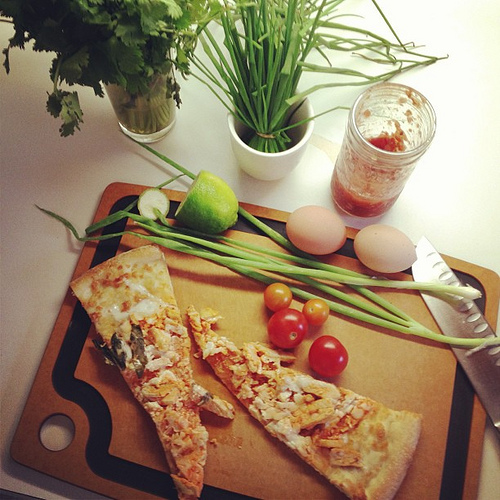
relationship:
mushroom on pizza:
[190, 385, 237, 423] [67, 245, 210, 499]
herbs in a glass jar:
[0, 0, 221, 139] [104, 56, 179, 145]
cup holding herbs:
[224, 86, 314, 186] [172, 1, 454, 153]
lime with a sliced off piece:
[171, 173, 241, 237] [137, 190, 170, 223]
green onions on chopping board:
[35, 135, 498, 355] [11, 182, 499, 499]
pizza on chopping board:
[67, 245, 210, 499] [11, 182, 499, 499]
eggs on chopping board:
[285, 203, 415, 274] [11, 182, 499, 499]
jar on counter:
[331, 79, 437, 222] [0, 0, 500, 499]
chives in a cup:
[172, 1, 454, 153] [224, 86, 314, 186]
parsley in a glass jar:
[0, 0, 221, 139] [104, 56, 179, 145]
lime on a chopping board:
[171, 173, 241, 237] [11, 182, 499, 499]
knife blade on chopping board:
[411, 234, 499, 429] [11, 182, 499, 499]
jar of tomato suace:
[331, 79, 437, 222] [331, 128, 405, 218]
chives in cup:
[172, 1, 454, 153] [224, 86, 314, 186]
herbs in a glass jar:
[45, 72, 83, 138] [104, 56, 179, 145]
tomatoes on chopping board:
[266, 283, 349, 380] [11, 182, 499, 499]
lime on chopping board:
[171, 173, 241, 237] [11, 182, 499, 499]